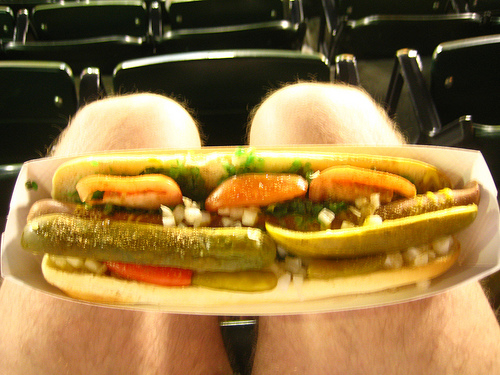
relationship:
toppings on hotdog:
[19, 165, 480, 292] [26, 182, 481, 231]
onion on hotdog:
[186, 208, 200, 221] [26, 182, 481, 231]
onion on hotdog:
[318, 206, 333, 225] [26, 182, 481, 231]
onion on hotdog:
[367, 215, 383, 226] [26, 182, 481, 231]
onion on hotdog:
[435, 237, 452, 254] [26, 182, 481, 231]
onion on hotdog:
[159, 202, 173, 215] [26, 182, 481, 231]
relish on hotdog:
[139, 166, 208, 205] [26, 182, 481, 231]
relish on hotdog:
[274, 197, 349, 229] [26, 182, 481, 231]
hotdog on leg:
[26, 182, 481, 231] [2, 278, 231, 374]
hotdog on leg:
[26, 182, 481, 231] [250, 279, 499, 373]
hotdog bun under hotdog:
[41, 152, 457, 308] [26, 182, 481, 231]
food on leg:
[41, 152, 457, 308] [2, 278, 231, 374]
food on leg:
[41, 152, 457, 308] [250, 279, 499, 373]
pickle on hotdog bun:
[21, 214, 275, 272] [52, 153, 440, 207]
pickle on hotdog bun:
[266, 205, 479, 258] [41, 152, 457, 308]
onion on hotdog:
[386, 253, 404, 269] [26, 182, 481, 231]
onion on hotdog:
[230, 209, 246, 219] [26, 182, 481, 231]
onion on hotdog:
[368, 191, 379, 208] [26, 182, 481, 231]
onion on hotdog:
[412, 253, 426, 264] [26, 182, 481, 231]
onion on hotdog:
[283, 255, 300, 271] [26, 182, 481, 231]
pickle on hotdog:
[21, 214, 275, 272] [26, 182, 481, 231]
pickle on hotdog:
[266, 205, 479, 258] [26, 182, 481, 231]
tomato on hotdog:
[207, 172, 307, 210] [26, 182, 481, 231]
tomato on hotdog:
[305, 166, 417, 202] [26, 182, 481, 231]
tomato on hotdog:
[76, 173, 182, 213] [26, 182, 481, 231]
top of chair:
[440, 115, 499, 141] [385, 36, 500, 146]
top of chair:
[328, 12, 483, 57] [319, 1, 484, 59]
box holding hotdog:
[2, 144, 499, 318] [26, 182, 481, 231]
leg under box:
[2, 278, 231, 374] [2, 144, 499, 318]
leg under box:
[250, 279, 499, 373] [2, 144, 499, 318]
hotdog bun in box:
[41, 152, 457, 308] [2, 144, 499, 318]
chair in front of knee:
[78, 50, 363, 147] [49, 92, 201, 155]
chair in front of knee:
[152, 4, 307, 48] [49, 92, 201, 155]